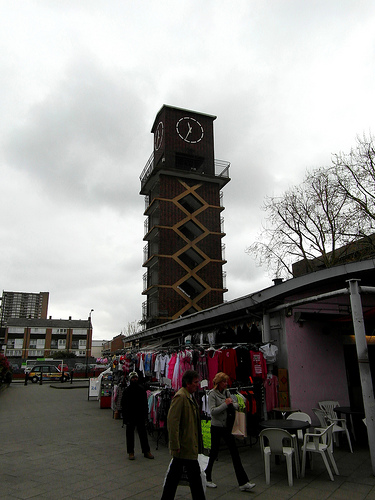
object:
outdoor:
[0, 0, 375, 498]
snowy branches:
[344, 227, 375, 261]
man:
[160, 369, 205, 498]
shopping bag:
[162, 452, 210, 495]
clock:
[175, 117, 205, 145]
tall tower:
[138, 104, 230, 330]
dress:
[259, 343, 279, 362]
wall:
[293, 314, 346, 415]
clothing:
[133, 349, 147, 376]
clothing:
[149, 351, 161, 378]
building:
[121, 261, 375, 475]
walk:
[1, 379, 374, 497]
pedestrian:
[204, 371, 255, 492]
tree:
[273, 173, 352, 280]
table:
[259, 416, 310, 469]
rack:
[94, 341, 293, 396]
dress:
[162, 355, 175, 386]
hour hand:
[188, 121, 192, 133]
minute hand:
[185, 127, 193, 140]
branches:
[356, 133, 374, 184]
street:
[2, 369, 97, 390]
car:
[27, 364, 69, 383]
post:
[25, 372, 29, 385]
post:
[40, 372, 43, 385]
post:
[61, 371, 64, 382]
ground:
[38, 347, 320, 496]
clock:
[153, 120, 163, 153]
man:
[120, 372, 155, 461]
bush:
[26, 357, 65, 381]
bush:
[0, 368, 13, 389]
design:
[173, 175, 211, 318]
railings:
[163, 149, 230, 177]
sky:
[24, 25, 330, 76]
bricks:
[0, 453, 34, 499]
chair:
[319, 399, 343, 443]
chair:
[258, 427, 300, 487]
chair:
[282, 408, 311, 441]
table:
[332, 406, 366, 449]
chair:
[299, 422, 340, 483]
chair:
[312, 407, 352, 454]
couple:
[160, 368, 255, 500]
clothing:
[223, 346, 238, 378]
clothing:
[170, 349, 192, 390]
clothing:
[203, 345, 220, 387]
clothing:
[165, 347, 175, 379]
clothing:
[109, 375, 128, 410]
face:
[177, 117, 202, 140]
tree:
[329, 139, 374, 261]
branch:
[252, 238, 294, 275]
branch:
[274, 206, 304, 245]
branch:
[274, 224, 303, 247]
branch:
[300, 203, 325, 244]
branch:
[308, 177, 326, 211]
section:
[173, 189, 209, 215]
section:
[173, 214, 208, 242]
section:
[173, 243, 211, 273]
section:
[174, 273, 211, 303]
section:
[170, 302, 201, 319]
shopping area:
[100, 304, 375, 476]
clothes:
[234, 345, 268, 387]